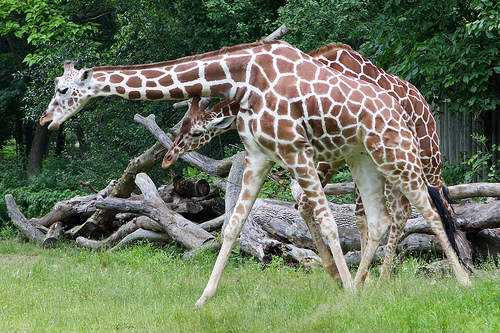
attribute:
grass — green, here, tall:
[3, 227, 498, 332]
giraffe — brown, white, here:
[38, 37, 477, 309]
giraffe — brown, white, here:
[162, 42, 474, 275]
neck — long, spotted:
[91, 39, 263, 102]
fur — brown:
[79, 41, 357, 71]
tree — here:
[26, 5, 102, 181]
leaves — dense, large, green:
[5, 1, 498, 137]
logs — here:
[0, 105, 499, 273]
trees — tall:
[4, 1, 499, 182]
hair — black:
[427, 183, 466, 259]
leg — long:
[193, 156, 272, 311]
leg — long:
[279, 148, 358, 294]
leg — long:
[342, 149, 393, 291]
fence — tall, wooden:
[417, 90, 498, 181]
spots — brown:
[90, 42, 437, 227]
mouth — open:
[40, 119, 57, 131]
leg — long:
[370, 131, 472, 286]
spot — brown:
[140, 65, 167, 81]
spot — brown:
[204, 60, 228, 81]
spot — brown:
[338, 47, 362, 74]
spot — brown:
[415, 118, 429, 138]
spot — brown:
[337, 104, 358, 128]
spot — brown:
[295, 58, 320, 83]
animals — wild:
[37, 37, 479, 310]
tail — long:
[404, 112, 462, 256]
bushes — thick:
[5, 141, 498, 231]